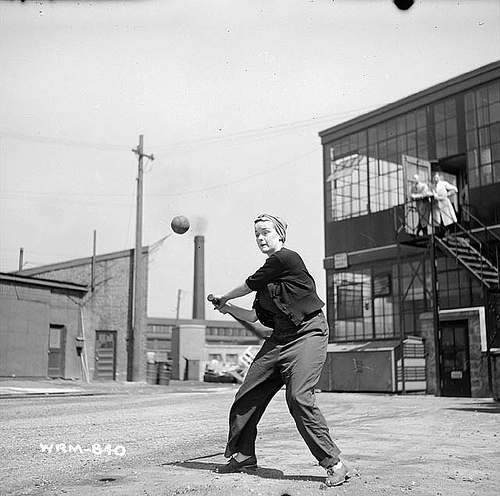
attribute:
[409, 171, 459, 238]
men — watching, standing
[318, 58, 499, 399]
building — large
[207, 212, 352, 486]
woman — playing, swinging bat, swing at softball, middle aged, making a  face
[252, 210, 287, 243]
bandana — beige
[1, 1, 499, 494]
photo — black, white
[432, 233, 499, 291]
ladder — metal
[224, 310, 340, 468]
pants — dark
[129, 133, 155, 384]
electrical pole — tall, wooden, very tall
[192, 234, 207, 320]
smokestack — for carbon emissions, tall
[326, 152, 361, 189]
window — open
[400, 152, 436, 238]
door — black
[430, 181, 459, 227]
coat — white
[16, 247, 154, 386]
building — brick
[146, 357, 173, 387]
barrels — metal, side by side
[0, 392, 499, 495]
parking lot — gravel paved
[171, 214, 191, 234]
ball — softball sized, airborne